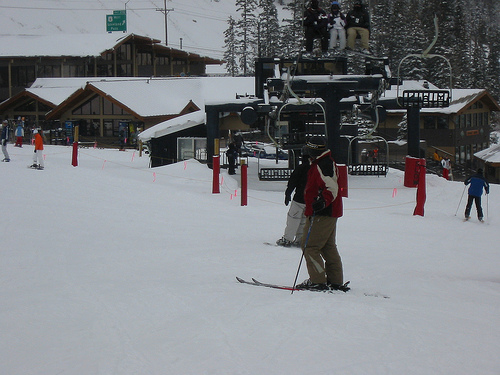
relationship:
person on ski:
[236, 138, 340, 220] [237, 220, 308, 253]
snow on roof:
[147, 99, 165, 105] [81, 63, 161, 109]